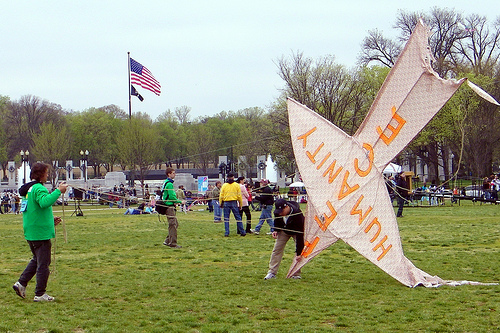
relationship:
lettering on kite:
[296, 109, 406, 261] [281, 21, 461, 285]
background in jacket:
[0, 149, 499, 197] [21, 186, 62, 240]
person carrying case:
[159, 167, 180, 246] [154, 200, 168, 213]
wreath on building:
[258, 161, 266, 170] [1, 159, 304, 200]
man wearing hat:
[266, 198, 307, 281] [273, 200, 286, 215]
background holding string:
[0, 149, 499, 197] [62, 138, 317, 236]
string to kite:
[62, 138, 317, 236] [281, 21, 461, 285]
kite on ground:
[281, 21, 461, 285] [0, 199, 499, 331]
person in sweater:
[238, 177, 259, 234] [241, 182, 249, 209]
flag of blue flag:
[129, 60, 162, 94] [128, 56, 162, 103]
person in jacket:
[219, 175, 246, 233] [218, 182, 242, 203]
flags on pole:
[127, 54, 162, 101] [125, 50, 133, 121]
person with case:
[159, 167, 180, 246] [154, 200, 168, 213]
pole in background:
[125, 50, 133, 121] [1, 73, 499, 169]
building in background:
[1, 159, 304, 200] [1, 73, 499, 169]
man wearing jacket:
[266, 198, 307, 281] [273, 209, 307, 248]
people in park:
[11, 162, 499, 299] [0, 117, 498, 331]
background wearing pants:
[0, 149, 499, 197] [26, 243, 52, 292]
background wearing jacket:
[0, 149, 499, 197] [21, 186, 62, 240]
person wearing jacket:
[219, 175, 246, 233] [218, 182, 242, 203]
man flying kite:
[266, 198, 307, 281] [281, 21, 461, 285]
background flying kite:
[0, 149, 499, 197] [281, 21, 461, 285]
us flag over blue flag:
[129, 60, 162, 94] [129, 84, 144, 102]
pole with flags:
[125, 50, 133, 121] [127, 54, 162, 101]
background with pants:
[0, 149, 499, 197] [26, 243, 52, 292]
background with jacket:
[0, 149, 499, 197] [21, 186, 62, 240]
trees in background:
[3, 102, 498, 162] [1, 73, 499, 169]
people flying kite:
[11, 162, 499, 299] [281, 21, 461, 285]